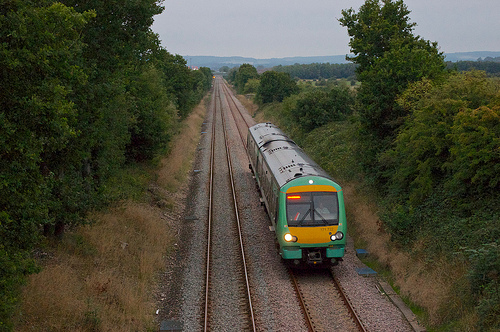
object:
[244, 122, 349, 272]
train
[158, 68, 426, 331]
rail road tracks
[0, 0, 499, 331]
bushes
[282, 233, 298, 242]
headlight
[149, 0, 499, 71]
sky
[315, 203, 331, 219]
person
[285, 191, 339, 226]
windshield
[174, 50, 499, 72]
mountains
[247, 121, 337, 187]
roof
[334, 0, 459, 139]
tree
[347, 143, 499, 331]
hillside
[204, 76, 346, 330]
lanes